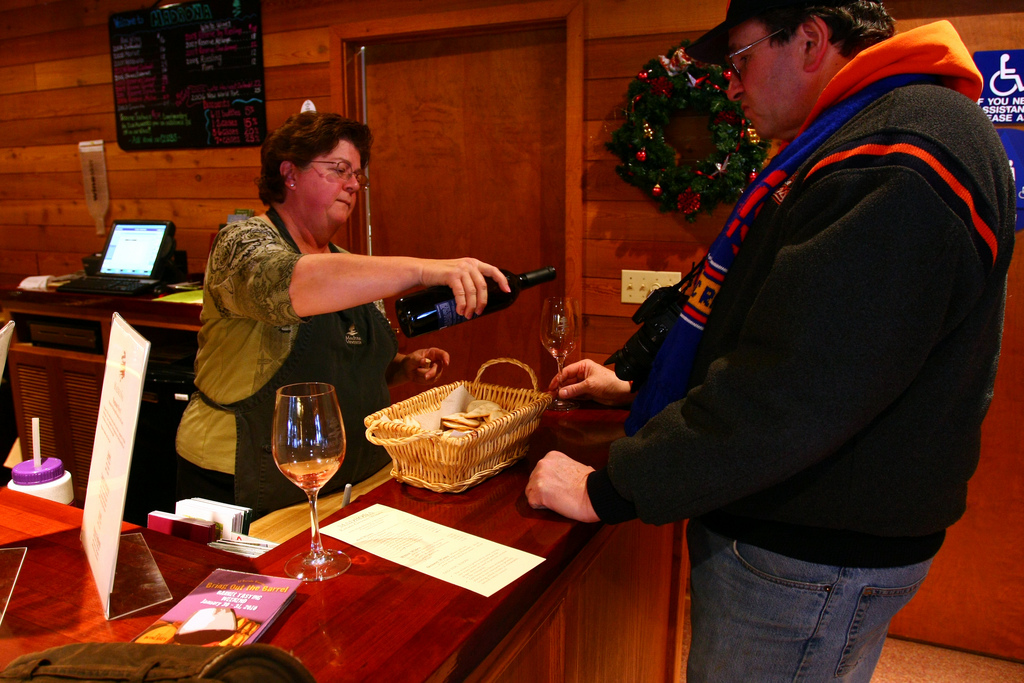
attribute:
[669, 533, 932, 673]
jeans — blue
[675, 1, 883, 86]
hat — black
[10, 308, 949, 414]
bottle — water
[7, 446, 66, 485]
lid — purple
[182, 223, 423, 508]
apron — black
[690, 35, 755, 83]
glasses — reading